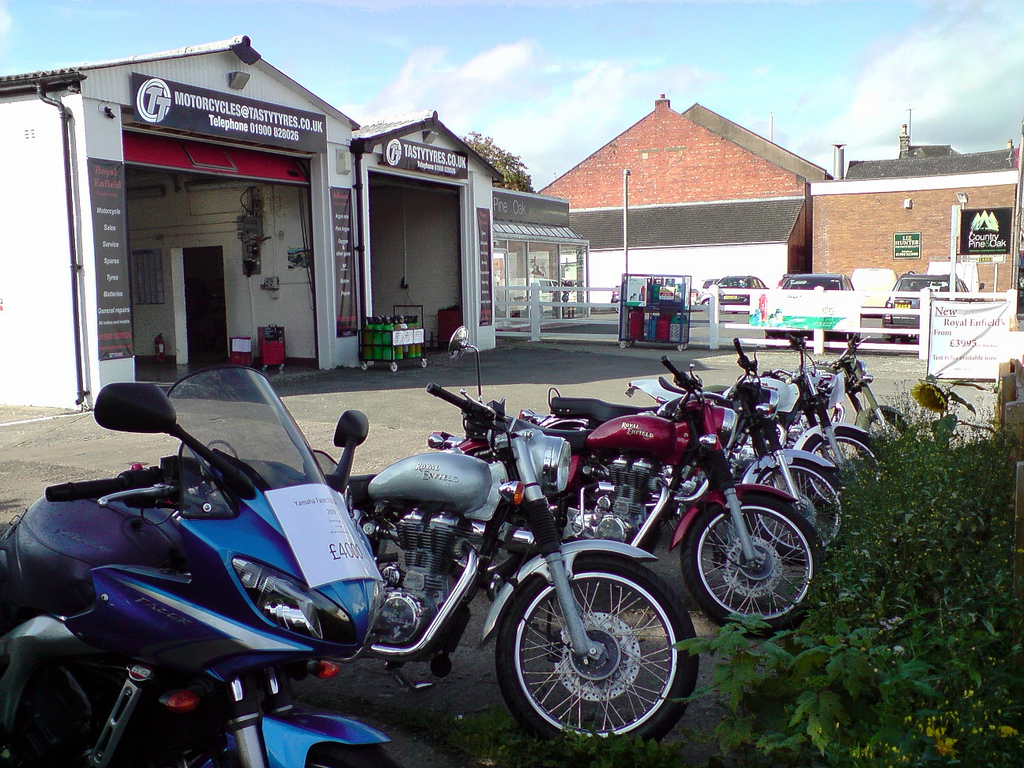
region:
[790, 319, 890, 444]
Motorcycle parked in the lot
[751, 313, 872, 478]
Motorcycle parked in the lot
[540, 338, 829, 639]
Motorcycle parked in the lot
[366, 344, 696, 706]
Motorcycle parked in the lot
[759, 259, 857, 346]
Car parked in the lot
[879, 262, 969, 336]
Car parked in the lot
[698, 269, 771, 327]
Car parked in the lot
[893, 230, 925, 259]
green plaque on the wall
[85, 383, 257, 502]
Mirror on a motorcycle.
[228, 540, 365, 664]
Front light on a motorcycle.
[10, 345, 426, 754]
Black and blue motorcycle.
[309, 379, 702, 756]
Silver and black motorcycle.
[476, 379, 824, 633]
Red and black motorcycle.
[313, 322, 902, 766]
Motorcycles lined up in a row.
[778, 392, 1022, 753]
Greeen weeds by motorcycles.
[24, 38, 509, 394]
Two opened garage doors.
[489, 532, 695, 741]
Front wheel of a motorcycle.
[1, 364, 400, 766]
A blue motorbike parked.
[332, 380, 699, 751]
A silver motorcycle parked.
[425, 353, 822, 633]
A parked red motorcycle.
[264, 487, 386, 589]
A white paper on a blue motorcycle front.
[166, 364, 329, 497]
Windshield on a blue motorcycle.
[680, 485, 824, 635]
Front black wheel on a red motorcycle.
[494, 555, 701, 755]
Front wheel on a silver motorcycle.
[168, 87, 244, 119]
The white word MOTORCYCLES on a black rectangle sign.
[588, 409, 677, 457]
A red motorcycle gas tank.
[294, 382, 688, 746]
The gray motorcycle next to the blue motorcycle.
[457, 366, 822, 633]
The burgundy motorcycle next to the gray motorcycle.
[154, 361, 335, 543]
The windshield of the blue motorcycle.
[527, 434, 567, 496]
The headlight of the gray motorcycle.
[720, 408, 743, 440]
The headlight of the maroon motorcycle.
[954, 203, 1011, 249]
The black sign on the building on the right.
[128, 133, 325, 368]
The garage with the red door that is open.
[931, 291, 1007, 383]
The white sign with black lettering on the posted fence.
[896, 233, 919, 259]
The green sign on the brick building on the right.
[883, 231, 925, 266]
green and white sign on the building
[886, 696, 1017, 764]
yellow flowers among the leaves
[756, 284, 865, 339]
sign on the white fence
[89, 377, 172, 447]
mirror on the motorcycle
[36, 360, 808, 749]
group of bikes parked on the road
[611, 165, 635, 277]
post in front of the building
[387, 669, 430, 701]
kickstand on the gray bike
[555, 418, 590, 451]
black seat of the red bike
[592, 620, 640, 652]
spokes on the wheel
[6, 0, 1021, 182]
the cloudy sky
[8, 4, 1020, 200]
A cloudy sky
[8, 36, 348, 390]
the garage to the left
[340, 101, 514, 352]
The garage to the right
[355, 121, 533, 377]
A garage to the right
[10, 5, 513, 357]
A set of garage buildings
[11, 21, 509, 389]
The set of garage buildings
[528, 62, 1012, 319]
A red brick building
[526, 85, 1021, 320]
The red brick building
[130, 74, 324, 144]
white and black sign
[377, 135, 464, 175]
white and black sign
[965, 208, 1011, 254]
green and white sign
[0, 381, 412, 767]
a motorcycle is parked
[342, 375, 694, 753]
a motorcycle is parked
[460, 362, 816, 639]
a motorcycle is parked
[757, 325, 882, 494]
a motorcycle is parked